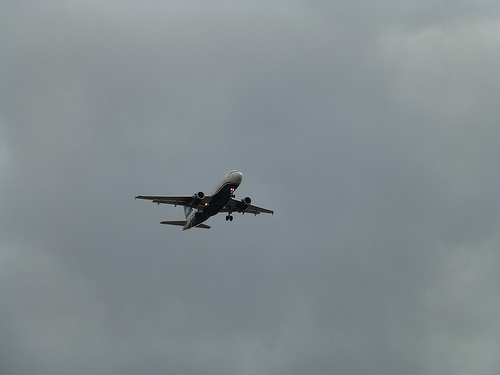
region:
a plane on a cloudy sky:
[8, 5, 497, 367]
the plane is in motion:
[128, 151, 285, 253]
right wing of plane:
[228, 200, 280, 217]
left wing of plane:
[134, 192, 194, 208]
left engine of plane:
[190, 186, 208, 204]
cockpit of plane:
[224, 165, 246, 187]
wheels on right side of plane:
[220, 210, 237, 224]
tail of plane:
[159, 216, 219, 233]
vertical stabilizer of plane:
[174, 205, 201, 224]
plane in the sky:
[117, 153, 269, 240]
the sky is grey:
[365, 323, 430, 362]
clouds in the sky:
[322, 254, 389, 338]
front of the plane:
[219, 173, 249, 189]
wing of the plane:
[137, 190, 197, 205]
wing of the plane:
[242, 200, 282, 217]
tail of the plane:
[150, 217, 215, 235]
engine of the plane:
[220, 210, 237, 225]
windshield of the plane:
[224, 169, 240, 175]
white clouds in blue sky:
[382, 79, 449, 161]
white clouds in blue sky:
[360, 221, 492, 298]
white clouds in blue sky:
[294, 249, 345, 310]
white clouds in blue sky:
[208, 46, 303, 87]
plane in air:
[117, 172, 289, 247]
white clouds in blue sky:
[370, 36, 455, 106]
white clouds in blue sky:
[347, 232, 402, 296]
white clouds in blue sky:
[228, 272, 282, 329]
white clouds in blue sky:
[177, 93, 222, 118]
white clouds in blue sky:
[101, 32, 173, 97]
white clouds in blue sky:
[84, 85, 131, 125]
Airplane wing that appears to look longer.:
[135, 193, 212, 212]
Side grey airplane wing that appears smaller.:
[218, 195, 275, 216]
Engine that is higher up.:
[236, 194, 252, 215]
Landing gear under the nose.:
[228, 191, 234, 198]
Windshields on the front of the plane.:
[227, 169, 239, 176]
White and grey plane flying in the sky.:
[134, 167, 275, 228]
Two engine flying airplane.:
[136, 169, 275, 233]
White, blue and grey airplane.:
[133, 169, 272, 231]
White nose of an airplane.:
[233, 171, 243, 178]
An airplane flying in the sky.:
[133, 169, 273, 231]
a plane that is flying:
[129, 156, 277, 245]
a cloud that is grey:
[235, 59, 472, 204]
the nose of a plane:
[225, 161, 248, 187]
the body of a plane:
[167, 172, 244, 231]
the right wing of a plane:
[126, 185, 211, 217]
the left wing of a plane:
[217, 181, 279, 231]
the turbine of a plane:
[187, 192, 209, 206]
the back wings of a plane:
[163, 215, 212, 238]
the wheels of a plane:
[220, 181, 242, 205]